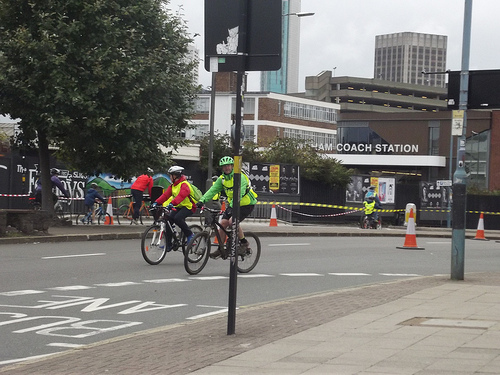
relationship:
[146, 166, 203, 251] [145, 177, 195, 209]
boy in a jacket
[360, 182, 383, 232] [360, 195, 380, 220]
father and son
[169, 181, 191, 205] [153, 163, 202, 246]
arm of person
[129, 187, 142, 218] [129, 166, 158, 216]
leg of a person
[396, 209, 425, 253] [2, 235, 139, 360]
cone in street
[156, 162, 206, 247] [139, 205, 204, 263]
boy on a bike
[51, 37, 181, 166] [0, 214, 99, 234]
tree in grass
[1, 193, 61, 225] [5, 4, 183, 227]
bench in park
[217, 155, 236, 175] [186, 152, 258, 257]
head of a person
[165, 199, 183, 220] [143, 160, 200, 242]
hand of a person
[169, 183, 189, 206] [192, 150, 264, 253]
arm of a person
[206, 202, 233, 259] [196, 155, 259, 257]
leg of a person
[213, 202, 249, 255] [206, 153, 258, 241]
leg of a person